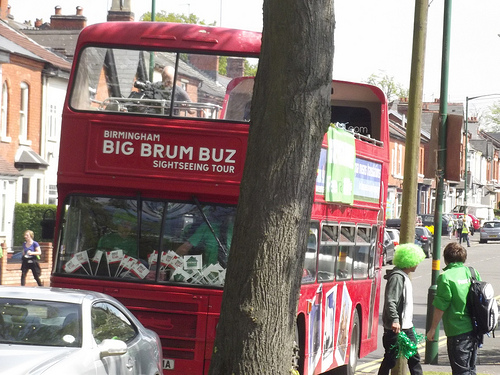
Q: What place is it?
A: It is a road.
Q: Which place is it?
A: It is a road.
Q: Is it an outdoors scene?
A: Yes, it is outdoors.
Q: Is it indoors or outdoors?
A: It is outdoors.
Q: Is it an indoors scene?
A: No, it is outdoors.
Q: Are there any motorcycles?
A: No, there are no motorcycles.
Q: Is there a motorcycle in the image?
A: No, there are no motorcycles.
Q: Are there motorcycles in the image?
A: No, there are no motorcycles.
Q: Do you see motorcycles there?
A: No, there are no motorcycles.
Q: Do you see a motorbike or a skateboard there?
A: No, there are no motorcycles or skateboards.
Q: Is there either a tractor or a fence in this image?
A: No, there are no fences or tractors.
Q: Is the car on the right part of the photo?
A: No, the car is on the left of the image.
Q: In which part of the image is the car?
A: The car is on the left of the image.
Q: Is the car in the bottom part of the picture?
A: Yes, the car is in the bottom of the image.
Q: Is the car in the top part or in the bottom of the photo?
A: The car is in the bottom of the image.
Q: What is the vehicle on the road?
A: The vehicle is a car.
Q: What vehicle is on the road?
A: The vehicle is a car.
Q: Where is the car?
A: The car is on the road.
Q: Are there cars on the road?
A: Yes, there is a car on the road.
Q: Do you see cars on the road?
A: Yes, there is a car on the road.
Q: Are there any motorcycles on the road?
A: No, there is a car on the road.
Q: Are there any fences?
A: No, there are no fences.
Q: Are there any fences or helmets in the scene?
A: No, there are no fences or helmets.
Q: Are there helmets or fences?
A: No, there are no fences or helmets.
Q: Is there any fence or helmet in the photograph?
A: No, there are no fences or helmets.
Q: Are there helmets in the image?
A: No, there are no helmets.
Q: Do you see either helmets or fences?
A: No, there are no helmets or fences.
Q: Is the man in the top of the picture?
A: Yes, the man is in the top of the image.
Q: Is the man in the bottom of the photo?
A: No, the man is in the top of the image.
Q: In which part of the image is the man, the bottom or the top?
A: The man is in the top of the image.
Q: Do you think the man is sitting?
A: Yes, the man is sitting.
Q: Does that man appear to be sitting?
A: Yes, the man is sitting.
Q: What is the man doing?
A: The man is sitting.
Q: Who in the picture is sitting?
A: The man is sitting.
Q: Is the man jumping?
A: No, the man is sitting.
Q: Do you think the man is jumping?
A: No, the man is sitting.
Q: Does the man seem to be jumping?
A: No, the man is sitting.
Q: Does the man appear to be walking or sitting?
A: The man is sitting.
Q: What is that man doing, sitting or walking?
A: The man is sitting.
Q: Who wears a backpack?
A: The man wears a backpack.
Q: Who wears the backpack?
A: The man wears a backpack.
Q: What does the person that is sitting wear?
A: The man wears a backpack.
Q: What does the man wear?
A: The man wears a backpack.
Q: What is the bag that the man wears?
A: The bag is a backpack.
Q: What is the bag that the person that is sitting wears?
A: The bag is a backpack.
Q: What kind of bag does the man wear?
A: The man wears a backpack.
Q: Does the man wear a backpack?
A: Yes, the man wears a backpack.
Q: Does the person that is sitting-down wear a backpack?
A: Yes, the man wears a backpack.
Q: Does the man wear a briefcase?
A: No, the man wears a backpack.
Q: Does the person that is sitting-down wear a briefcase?
A: No, the man wears a backpack.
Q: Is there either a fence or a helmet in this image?
A: No, there are no fences or helmets.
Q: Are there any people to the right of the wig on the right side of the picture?
A: Yes, there is a person to the right of the wig.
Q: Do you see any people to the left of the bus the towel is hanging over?
A: No, the person is to the right of the bus.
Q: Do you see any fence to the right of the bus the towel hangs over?
A: No, there is a person to the right of the bus.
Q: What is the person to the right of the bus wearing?
A: The person is wearing a wig.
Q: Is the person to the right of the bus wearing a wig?
A: Yes, the person is wearing a wig.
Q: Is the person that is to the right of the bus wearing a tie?
A: No, the person is wearing a wig.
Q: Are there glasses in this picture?
A: No, there are no glasses.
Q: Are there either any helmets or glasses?
A: No, there are no glasses or helmets.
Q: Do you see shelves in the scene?
A: No, there are no shelves.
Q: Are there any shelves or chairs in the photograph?
A: No, there are no shelves or chairs.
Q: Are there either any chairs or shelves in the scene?
A: No, there are no shelves or chairs.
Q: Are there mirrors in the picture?
A: Yes, there is a mirror.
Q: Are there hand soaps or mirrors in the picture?
A: Yes, there is a mirror.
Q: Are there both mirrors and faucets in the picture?
A: No, there is a mirror but no faucets.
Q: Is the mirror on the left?
A: Yes, the mirror is on the left of the image.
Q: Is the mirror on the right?
A: No, the mirror is on the left of the image.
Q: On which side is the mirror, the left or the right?
A: The mirror is on the left of the image.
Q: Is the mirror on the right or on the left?
A: The mirror is on the left of the image.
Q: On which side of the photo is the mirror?
A: The mirror is on the left of the image.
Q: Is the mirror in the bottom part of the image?
A: Yes, the mirror is in the bottom of the image.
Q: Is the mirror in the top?
A: No, the mirror is in the bottom of the image.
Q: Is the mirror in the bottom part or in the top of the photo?
A: The mirror is in the bottom of the image.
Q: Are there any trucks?
A: No, there are no trucks.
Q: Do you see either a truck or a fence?
A: No, there are no trucks or fences.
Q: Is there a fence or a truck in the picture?
A: No, there are no trucks or fences.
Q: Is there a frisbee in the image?
A: No, there are no frisbees.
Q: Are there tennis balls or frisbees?
A: No, there are no frisbees or tennis balls.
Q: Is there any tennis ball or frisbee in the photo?
A: No, there are no frisbees or tennis balls.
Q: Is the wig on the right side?
A: Yes, the wig is on the right of the image.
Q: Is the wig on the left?
A: No, the wig is on the right of the image.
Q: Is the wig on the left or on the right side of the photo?
A: The wig is on the right of the image.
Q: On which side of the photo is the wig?
A: The wig is on the right of the image.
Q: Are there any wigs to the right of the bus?
A: Yes, there is a wig to the right of the bus.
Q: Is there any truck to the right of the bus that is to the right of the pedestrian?
A: No, there is a wig to the right of the bus.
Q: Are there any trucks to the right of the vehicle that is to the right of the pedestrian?
A: No, there is a wig to the right of the bus.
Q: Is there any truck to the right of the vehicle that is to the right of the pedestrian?
A: No, there is a wig to the right of the bus.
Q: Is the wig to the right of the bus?
A: Yes, the wig is to the right of the bus.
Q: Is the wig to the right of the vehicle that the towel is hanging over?
A: Yes, the wig is to the right of the bus.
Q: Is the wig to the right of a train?
A: No, the wig is to the right of the bus.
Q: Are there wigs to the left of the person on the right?
A: Yes, there is a wig to the left of the person.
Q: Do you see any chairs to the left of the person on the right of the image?
A: No, there is a wig to the left of the person.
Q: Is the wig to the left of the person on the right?
A: Yes, the wig is to the left of the person.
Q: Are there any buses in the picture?
A: Yes, there is a bus.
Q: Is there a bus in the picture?
A: Yes, there is a bus.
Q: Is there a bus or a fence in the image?
A: Yes, there is a bus.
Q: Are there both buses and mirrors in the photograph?
A: Yes, there are both a bus and a mirror.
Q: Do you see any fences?
A: No, there are no fences.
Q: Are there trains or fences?
A: No, there are no fences or trains.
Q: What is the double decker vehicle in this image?
A: The vehicle is a bus.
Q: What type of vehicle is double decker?
A: The vehicle is a bus.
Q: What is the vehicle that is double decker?
A: The vehicle is a bus.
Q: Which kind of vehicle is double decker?
A: The vehicle is a bus.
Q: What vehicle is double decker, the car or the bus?
A: The bus is double decker.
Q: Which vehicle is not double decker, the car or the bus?
A: The car is not double decker.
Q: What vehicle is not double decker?
A: The vehicle is a car.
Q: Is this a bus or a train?
A: This is a bus.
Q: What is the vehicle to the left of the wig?
A: The vehicle is a bus.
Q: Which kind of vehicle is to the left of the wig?
A: The vehicle is a bus.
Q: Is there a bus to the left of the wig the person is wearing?
A: Yes, there is a bus to the left of the wig.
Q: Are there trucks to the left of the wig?
A: No, there is a bus to the left of the wig.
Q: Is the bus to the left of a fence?
A: No, the bus is to the left of the wig.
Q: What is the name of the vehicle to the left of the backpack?
A: The vehicle is a bus.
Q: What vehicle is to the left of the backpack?
A: The vehicle is a bus.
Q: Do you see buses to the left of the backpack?
A: Yes, there is a bus to the left of the backpack.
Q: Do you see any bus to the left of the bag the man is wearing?
A: Yes, there is a bus to the left of the backpack.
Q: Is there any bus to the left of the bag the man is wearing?
A: Yes, there is a bus to the left of the backpack.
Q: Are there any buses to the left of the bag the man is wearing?
A: Yes, there is a bus to the left of the backpack.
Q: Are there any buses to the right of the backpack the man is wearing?
A: No, the bus is to the left of the backpack.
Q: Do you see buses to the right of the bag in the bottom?
A: No, the bus is to the left of the backpack.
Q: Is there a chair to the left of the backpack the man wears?
A: No, there is a bus to the left of the backpack.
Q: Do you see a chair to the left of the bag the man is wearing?
A: No, there is a bus to the left of the backpack.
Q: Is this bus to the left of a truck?
A: No, the bus is to the left of the backpack.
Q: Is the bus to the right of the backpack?
A: No, the bus is to the left of the backpack.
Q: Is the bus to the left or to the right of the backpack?
A: The bus is to the left of the backpack.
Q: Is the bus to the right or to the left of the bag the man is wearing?
A: The bus is to the left of the backpack.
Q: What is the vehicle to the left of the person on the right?
A: The vehicle is a bus.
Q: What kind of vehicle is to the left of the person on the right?
A: The vehicle is a bus.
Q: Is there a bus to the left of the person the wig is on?
A: Yes, there is a bus to the left of the person.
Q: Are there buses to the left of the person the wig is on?
A: Yes, there is a bus to the left of the person.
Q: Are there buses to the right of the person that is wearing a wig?
A: No, the bus is to the left of the person.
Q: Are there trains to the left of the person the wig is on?
A: No, there is a bus to the left of the person.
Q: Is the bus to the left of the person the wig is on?
A: Yes, the bus is to the left of the person.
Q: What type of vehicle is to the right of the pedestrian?
A: The vehicle is a bus.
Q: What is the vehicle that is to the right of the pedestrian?
A: The vehicle is a bus.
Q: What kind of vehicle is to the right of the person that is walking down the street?
A: The vehicle is a bus.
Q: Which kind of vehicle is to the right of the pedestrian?
A: The vehicle is a bus.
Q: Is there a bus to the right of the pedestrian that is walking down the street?
A: Yes, there is a bus to the right of the pedestrian.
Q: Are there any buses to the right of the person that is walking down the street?
A: Yes, there is a bus to the right of the pedestrian.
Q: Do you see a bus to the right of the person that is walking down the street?
A: Yes, there is a bus to the right of the pedestrian.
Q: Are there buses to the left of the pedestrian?
A: No, the bus is to the right of the pedestrian.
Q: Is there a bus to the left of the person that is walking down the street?
A: No, the bus is to the right of the pedestrian.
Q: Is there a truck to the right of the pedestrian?
A: No, there is a bus to the right of the pedestrian.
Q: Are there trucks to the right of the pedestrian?
A: No, there is a bus to the right of the pedestrian.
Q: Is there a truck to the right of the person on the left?
A: No, there is a bus to the right of the pedestrian.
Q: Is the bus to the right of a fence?
A: No, the bus is to the right of a pedestrian.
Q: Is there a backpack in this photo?
A: Yes, there is a backpack.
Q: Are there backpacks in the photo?
A: Yes, there is a backpack.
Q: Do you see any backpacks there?
A: Yes, there is a backpack.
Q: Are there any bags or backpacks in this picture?
A: Yes, there is a backpack.